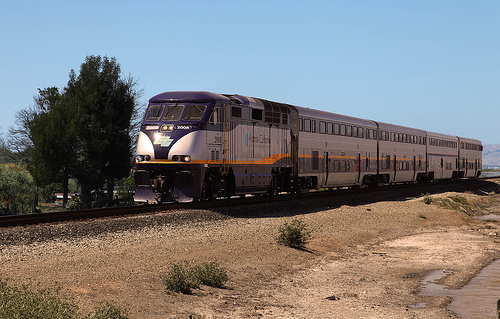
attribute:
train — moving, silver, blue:
[133, 91, 482, 203]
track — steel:
[1, 175, 500, 227]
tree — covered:
[57, 166, 72, 208]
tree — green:
[64, 53, 115, 207]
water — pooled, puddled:
[403, 257, 500, 319]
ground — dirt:
[1, 180, 499, 318]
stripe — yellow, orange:
[194, 152, 430, 165]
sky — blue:
[1, 1, 499, 145]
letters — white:
[153, 135, 173, 148]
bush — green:
[162, 268, 191, 293]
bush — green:
[90, 303, 125, 318]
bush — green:
[1, 282, 80, 319]